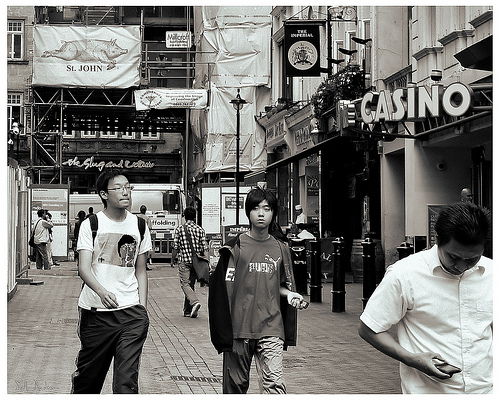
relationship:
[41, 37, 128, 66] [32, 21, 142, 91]
pig appears on sign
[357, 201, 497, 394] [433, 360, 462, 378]
guy carrying a cell phone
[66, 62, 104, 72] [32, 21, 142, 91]
st john written on sign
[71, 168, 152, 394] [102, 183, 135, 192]
guy wearing glasses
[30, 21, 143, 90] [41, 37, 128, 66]
banner has picture of a pig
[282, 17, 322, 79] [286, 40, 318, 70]
banner has a seal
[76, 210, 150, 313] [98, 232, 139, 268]
shirt depicts beatles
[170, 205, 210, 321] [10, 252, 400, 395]
man walking on street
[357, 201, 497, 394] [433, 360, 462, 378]
guy looking at cell phone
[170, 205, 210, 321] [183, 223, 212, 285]
man carrying a backpack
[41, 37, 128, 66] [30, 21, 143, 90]
pig sitting on a banner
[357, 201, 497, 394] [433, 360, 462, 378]
guy looking at h cell phone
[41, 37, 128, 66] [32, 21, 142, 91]
pig has been drawn on a sign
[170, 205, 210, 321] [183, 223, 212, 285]
man wearing a backpack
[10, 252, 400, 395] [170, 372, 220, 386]
street has a grate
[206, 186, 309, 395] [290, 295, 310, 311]
man holding cell phone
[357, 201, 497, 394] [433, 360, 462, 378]
guy looking at a cell phone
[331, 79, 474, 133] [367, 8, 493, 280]
sign attached to a building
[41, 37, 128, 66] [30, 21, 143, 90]
pig appears on a banner